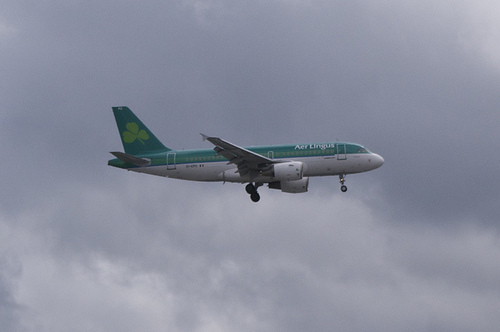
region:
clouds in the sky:
[31, 201, 473, 276]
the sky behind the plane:
[8, 24, 498, 101]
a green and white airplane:
[100, 92, 385, 193]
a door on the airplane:
[336, 145, 343, 155]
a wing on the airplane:
[200, 130, 270, 180]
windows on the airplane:
[275, 150, 326, 157]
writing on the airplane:
[297, 140, 332, 147]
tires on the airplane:
[239, 179, 264, 202]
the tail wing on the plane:
[111, 108, 153, 144]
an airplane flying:
[100, 103, 385, 215]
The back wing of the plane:
[103, 93, 166, 153]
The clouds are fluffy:
[24, 250, 257, 329]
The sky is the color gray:
[142, 20, 454, 118]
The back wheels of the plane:
[233, 176, 265, 206]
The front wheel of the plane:
[336, 175, 351, 195]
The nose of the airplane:
[368, 146, 387, 176]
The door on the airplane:
[331, 138, 351, 165]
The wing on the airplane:
[199, 130, 281, 169]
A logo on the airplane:
[118, 120, 154, 147]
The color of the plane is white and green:
[168, 139, 364, 184]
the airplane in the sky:
[107, 105, 384, 200]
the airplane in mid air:
[107, 105, 384, 202]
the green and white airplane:
[106, 105, 383, 201]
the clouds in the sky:
[0, 0, 499, 329]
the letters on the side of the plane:
[293, 143, 334, 149]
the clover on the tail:
[122, 120, 149, 144]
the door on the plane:
[335, 143, 346, 160]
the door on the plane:
[165, 150, 176, 170]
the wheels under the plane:
[244, 180, 347, 200]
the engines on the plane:
[272, 161, 309, 193]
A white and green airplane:
[96, 59, 437, 238]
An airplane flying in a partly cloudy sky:
[7, 5, 498, 310]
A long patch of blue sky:
[1, 123, 485, 182]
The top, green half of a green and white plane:
[98, 79, 384, 157]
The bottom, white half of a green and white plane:
[119, 157, 420, 207]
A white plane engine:
[233, 152, 320, 182]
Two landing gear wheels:
[242, 167, 272, 218]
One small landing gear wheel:
[328, 180, 358, 200]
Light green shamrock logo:
[108, 106, 168, 153]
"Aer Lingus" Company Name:
[289, 135, 353, 155]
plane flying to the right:
[95, 92, 399, 207]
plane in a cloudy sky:
[66, 73, 420, 260]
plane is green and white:
[96, 90, 396, 202]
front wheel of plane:
[333, 175, 353, 197]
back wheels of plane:
[243, 171, 264, 206]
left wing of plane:
[198, 128, 272, 168]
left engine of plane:
[256, 154, 309, 186]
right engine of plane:
[275, 174, 317, 196]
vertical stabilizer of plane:
[106, 94, 174, 151]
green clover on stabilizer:
[111, 99, 164, 152]